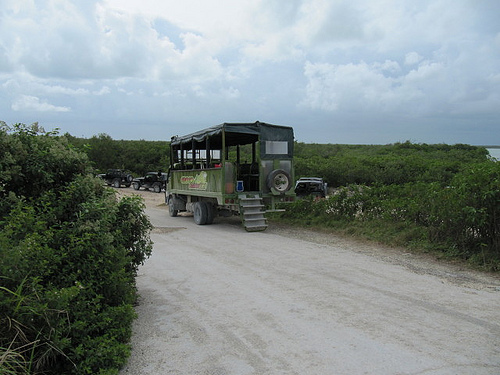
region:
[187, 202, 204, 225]
that is a wheel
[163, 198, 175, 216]
that is a wheel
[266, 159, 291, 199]
that is a wheel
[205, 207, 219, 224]
that is a wheel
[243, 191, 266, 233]
a flight t of stairs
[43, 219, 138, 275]
this is a bush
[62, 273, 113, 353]
this is a bush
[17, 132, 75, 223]
this is a bush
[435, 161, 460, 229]
this is a bush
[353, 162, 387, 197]
this is a bush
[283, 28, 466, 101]
this is the sky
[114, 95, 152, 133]
the sky is blue in color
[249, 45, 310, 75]
these are the clouds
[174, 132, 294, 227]
this is a lorry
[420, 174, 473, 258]
this is a tree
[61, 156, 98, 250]
the leaves are green in color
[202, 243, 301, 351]
this is a road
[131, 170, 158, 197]
this is a vehicle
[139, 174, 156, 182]
the vehicle is black in color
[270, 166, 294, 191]
this is a wheel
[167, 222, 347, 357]
a narrow dirt road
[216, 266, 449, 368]
a narrow dirt road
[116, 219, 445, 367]
a narrow dirt road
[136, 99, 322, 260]
the truck is parked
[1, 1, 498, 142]
THE SKIES ARE CLOUDY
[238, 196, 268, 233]
THESE ARE SMALL STEPS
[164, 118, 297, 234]
THIS IS A TRUCK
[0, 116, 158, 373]
THIS IS A BUSH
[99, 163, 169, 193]
THERE ARE TWO CARS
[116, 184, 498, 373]
THIS IS A ROADWAY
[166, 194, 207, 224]
THESE ARE TWO WHEELS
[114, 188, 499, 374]
THIS A DIRT CONCRETE ROAD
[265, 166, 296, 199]
A WHEEL ON THE BACK OF THE TRUCK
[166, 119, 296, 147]
THE TOP OF THE BUS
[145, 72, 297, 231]
green truck on road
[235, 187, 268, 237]
grey steps on truck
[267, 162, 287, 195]
tire on back of truck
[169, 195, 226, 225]
truck has black tires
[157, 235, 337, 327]
road is light brown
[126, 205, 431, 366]
road is dusty and dry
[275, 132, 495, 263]
green bushes next to road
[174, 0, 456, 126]
grey and cloudy sky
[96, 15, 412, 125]
clouds in sky are puffy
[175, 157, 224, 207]
green logo on truck